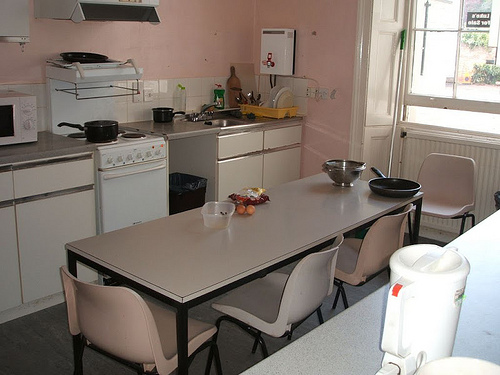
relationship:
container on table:
[200, 196, 237, 228] [61, 158, 424, 314]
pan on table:
[366, 161, 421, 198] [61, 158, 424, 314]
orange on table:
[245, 199, 256, 220] [61, 158, 424, 314]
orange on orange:
[236, 210, 245, 218] [245, 199, 256, 220]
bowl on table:
[320, 155, 368, 187] [63, 152, 423, 302]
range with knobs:
[46, 56, 169, 287] [115, 153, 125, 162]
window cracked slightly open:
[400, 4, 483, 135] [403, 108, 481, 128]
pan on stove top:
[55, 117, 119, 145] [68, 120, 165, 149]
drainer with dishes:
[238, 101, 300, 118] [253, 86, 292, 105]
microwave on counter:
[6, 88, 39, 148] [4, 128, 98, 165]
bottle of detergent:
[210, 80, 226, 113] [214, 96, 221, 106]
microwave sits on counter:
[6, 88, 39, 148] [3, 128, 94, 168]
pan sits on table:
[366, 161, 421, 198] [59, 133, 426, 345]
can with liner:
[170, 167, 207, 214] [172, 171, 205, 205]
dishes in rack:
[253, 86, 292, 105] [237, 102, 300, 118]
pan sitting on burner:
[55, 117, 119, 145] [81, 136, 118, 146]